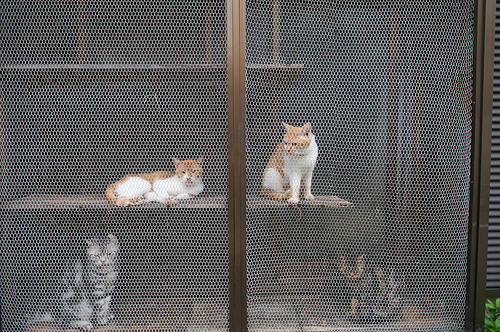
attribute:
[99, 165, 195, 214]
cat — white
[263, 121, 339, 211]
cat — white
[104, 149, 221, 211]
cat — tan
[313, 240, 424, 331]
cat — brown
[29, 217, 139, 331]
cat — grey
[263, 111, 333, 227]
cat — orange, white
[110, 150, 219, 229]
cat — white, orange, small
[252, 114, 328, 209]
cat — tan, orange, white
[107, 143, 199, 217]
cat — white, orange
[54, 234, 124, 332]
cat — black and grey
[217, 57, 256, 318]
frame bar — wooden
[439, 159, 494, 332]
frame bar — wooden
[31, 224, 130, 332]
cat — gray and black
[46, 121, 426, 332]
cats — four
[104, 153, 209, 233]
cat — orange and white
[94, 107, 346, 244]
cat —  orange and white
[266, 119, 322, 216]
cat — small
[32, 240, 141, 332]
cat — small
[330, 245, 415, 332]
cat — small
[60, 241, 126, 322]
cat — small